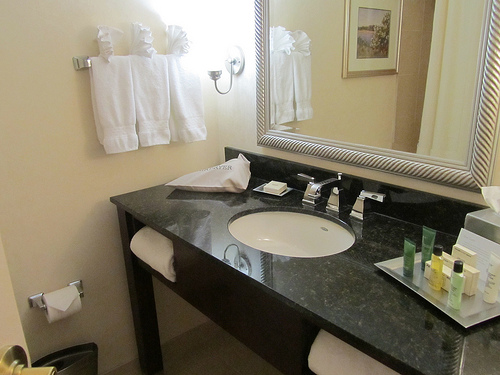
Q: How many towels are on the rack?
A: 3.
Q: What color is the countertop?
A: Black.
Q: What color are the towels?
A: White.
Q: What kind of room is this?
A: Bathroom.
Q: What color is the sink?
A: White.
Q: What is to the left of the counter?
A: Toilet paper.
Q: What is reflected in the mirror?
A: A picture.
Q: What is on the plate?
A: Toiletries.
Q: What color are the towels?
A: White.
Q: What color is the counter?
A: Black.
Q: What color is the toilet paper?
A: White.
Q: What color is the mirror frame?
A: White.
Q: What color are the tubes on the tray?
A: Green.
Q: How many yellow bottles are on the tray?
A: 1.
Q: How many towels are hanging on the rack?
A: 3.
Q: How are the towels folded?
A: Accordion- style.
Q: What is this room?
A: Bathroom.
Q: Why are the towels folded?
A: For new guests.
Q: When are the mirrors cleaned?
A: Every day.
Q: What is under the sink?
A: Paper towel rolls.